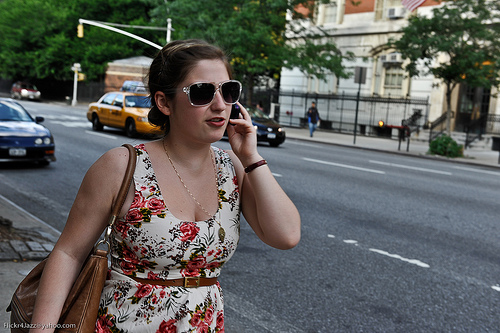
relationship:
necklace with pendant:
[158, 140, 228, 242] [216, 227, 228, 246]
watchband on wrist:
[244, 159, 268, 173] [237, 149, 276, 180]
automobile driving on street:
[0, 95, 60, 175] [12, 98, 499, 327]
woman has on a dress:
[28, 37, 306, 329] [72, 141, 247, 332]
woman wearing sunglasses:
[24, 37, 306, 332] [164, 74, 242, 109]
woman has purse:
[24, 37, 306, 332] [5, 139, 142, 328]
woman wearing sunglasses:
[28, 37, 306, 329] [167, 79, 245, 109]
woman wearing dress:
[28, 37, 306, 329] [72, 141, 247, 332]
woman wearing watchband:
[28, 37, 306, 329] [244, 159, 268, 173]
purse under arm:
[5, 139, 142, 328] [28, 147, 130, 330]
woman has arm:
[28, 37, 306, 329] [28, 147, 130, 330]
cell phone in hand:
[228, 102, 241, 123] [228, 100, 262, 161]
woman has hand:
[28, 37, 306, 329] [228, 100, 262, 161]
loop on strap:
[93, 235, 114, 256] [94, 143, 134, 257]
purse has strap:
[5, 139, 142, 328] [94, 143, 134, 257]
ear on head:
[149, 85, 177, 116] [145, 38, 244, 148]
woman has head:
[28, 37, 306, 329] [145, 38, 244, 148]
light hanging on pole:
[76, 24, 85, 38] [73, 17, 173, 51]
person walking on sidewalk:
[306, 101, 323, 138] [279, 122, 497, 176]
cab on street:
[84, 87, 162, 140] [12, 98, 499, 327]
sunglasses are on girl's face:
[174, 79, 242, 107] [171, 56, 244, 146]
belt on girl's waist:
[135, 273, 224, 293] [108, 243, 235, 308]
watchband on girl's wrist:
[244, 159, 268, 173] [234, 144, 273, 178]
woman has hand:
[24, 37, 306, 332] [228, 100, 262, 161]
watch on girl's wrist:
[244, 159, 268, 174] [239, 153, 271, 173]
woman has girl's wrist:
[28, 37, 306, 329] [239, 153, 271, 173]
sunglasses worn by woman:
[161, 79, 244, 108] [28, 37, 306, 329]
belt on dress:
[123, 274, 220, 289] [117, 194, 247, 327]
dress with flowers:
[123, 168, 255, 328] [180, 250, 206, 269]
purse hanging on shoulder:
[5, 142, 138, 332] [86, 138, 142, 210]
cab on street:
[83, 90, 166, 139] [69, 109, 112, 140]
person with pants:
[297, 94, 331, 148] [302, 115, 318, 132]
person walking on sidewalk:
[297, 94, 331, 148] [311, 128, 359, 144]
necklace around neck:
[162, 140, 223, 236] [168, 135, 207, 159]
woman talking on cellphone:
[24, 37, 306, 332] [218, 93, 267, 146]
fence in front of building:
[311, 81, 378, 136] [288, 1, 412, 88]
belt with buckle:
[123, 274, 220, 289] [172, 266, 199, 292]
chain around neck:
[167, 167, 211, 217] [171, 136, 208, 162]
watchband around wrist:
[245, 157, 271, 177] [244, 149, 276, 180]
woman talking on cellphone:
[24, 37, 306, 332] [226, 98, 253, 124]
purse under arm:
[5, 142, 138, 332] [28, 222, 98, 303]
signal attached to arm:
[71, 18, 91, 51] [82, 19, 150, 49]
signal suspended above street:
[77, 24, 85, 37] [0, 97, 497, 330]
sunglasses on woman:
[161, 79, 244, 108] [100, 47, 345, 305]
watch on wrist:
[236, 149, 270, 179] [240, 144, 270, 173]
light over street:
[71, 21, 87, 43] [39, 96, 91, 118]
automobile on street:
[0, 96, 58, 170] [4, 161, 77, 193]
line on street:
[360, 225, 433, 273] [351, 215, 463, 313]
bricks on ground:
[7, 222, 34, 253] [15, 192, 55, 233]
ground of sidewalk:
[15, 192, 55, 233] [23, 200, 54, 222]